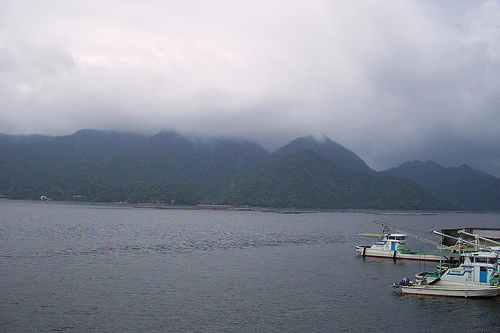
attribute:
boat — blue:
[391, 256, 499, 300]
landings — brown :
[121, 189, 498, 224]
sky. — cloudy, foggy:
[0, 0, 498, 155]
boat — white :
[413, 249, 498, 289]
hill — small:
[382, 162, 498, 197]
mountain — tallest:
[271, 138, 383, 172]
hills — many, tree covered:
[49, 127, 442, 214]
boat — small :
[388, 252, 498, 305]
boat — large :
[394, 256, 499, 296]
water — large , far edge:
[3, 211, 498, 331]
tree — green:
[10, 124, 498, 229]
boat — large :
[389, 244, 494, 302]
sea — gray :
[0, 200, 498, 332]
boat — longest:
[356, 225, 443, 265]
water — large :
[20, 206, 360, 331]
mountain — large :
[3, 124, 498, 214]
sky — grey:
[188, 28, 413, 100]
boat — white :
[361, 220, 440, 262]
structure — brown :
[447, 221, 474, 242]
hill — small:
[25, 108, 425, 211]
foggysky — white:
[3, 7, 493, 139]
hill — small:
[71, 74, 446, 234]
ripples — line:
[167, 216, 337, 261]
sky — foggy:
[1, 2, 498, 141]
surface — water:
[4, 200, 452, 324]